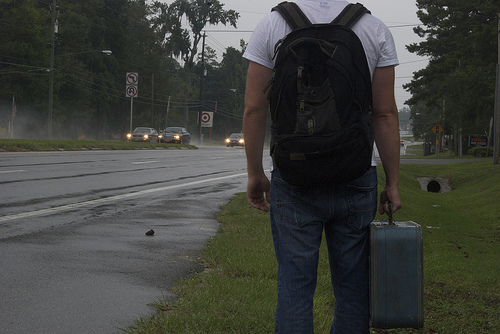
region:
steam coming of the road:
[0, 100, 125, 150]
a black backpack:
[270, 1, 372, 205]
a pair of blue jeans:
[254, 158, 384, 330]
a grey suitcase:
[364, 196, 429, 333]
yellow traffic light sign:
[425, 118, 447, 139]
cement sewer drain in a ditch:
[417, 170, 457, 208]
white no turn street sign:
[118, 63, 143, 133]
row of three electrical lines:
[2, 50, 257, 115]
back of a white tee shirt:
[238, 1, 398, 81]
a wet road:
[0, 147, 248, 291]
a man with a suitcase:
[237, 0, 431, 327]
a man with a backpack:
[252, 1, 419, 193]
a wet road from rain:
[10, 146, 282, 261]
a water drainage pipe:
[413, 170, 454, 204]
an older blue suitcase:
[369, 206, 433, 331]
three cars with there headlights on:
[122, 111, 252, 156]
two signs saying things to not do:
[121, 68, 141, 99]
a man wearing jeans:
[240, 1, 379, 323]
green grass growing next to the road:
[215, 157, 484, 322]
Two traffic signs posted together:
[115, 65, 146, 104]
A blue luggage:
[373, 195, 425, 332]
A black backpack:
[278, 4, 365, 175]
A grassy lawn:
[197, 280, 258, 322]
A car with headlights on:
[160, 127, 188, 147]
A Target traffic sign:
[194, 105, 219, 132]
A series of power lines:
[147, 89, 190, 115]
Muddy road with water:
[6, 188, 139, 229]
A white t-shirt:
[240, 2, 406, 65]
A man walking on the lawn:
[241, 10, 405, 332]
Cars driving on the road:
[111, 103, 205, 151]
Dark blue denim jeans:
[276, 174, 368, 327]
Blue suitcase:
[360, 215, 434, 332]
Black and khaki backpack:
[261, 0, 376, 192]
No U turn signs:
[23, 65, 156, 102]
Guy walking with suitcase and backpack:
[138, 5, 452, 325]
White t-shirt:
[233, 12, 276, 77]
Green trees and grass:
[419, 46, 499, 245]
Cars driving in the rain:
[23, 40, 242, 215]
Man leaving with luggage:
[201, 2, 448, 332]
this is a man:
[244, 1, 409, 328]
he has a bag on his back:
[267, 3, 372, 182]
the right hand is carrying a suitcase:
[366, 186, 426, 327]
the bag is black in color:
[270, 1, 377, 196]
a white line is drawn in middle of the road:
[1, 146, 217, 218]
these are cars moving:
[117, 124, 244, 147]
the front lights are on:
[126, 133, 187, 138]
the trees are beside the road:
[416, 1, 498, 141]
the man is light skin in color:
[382, 94, 391, 102]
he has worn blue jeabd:
[271, 178, 370, 330]